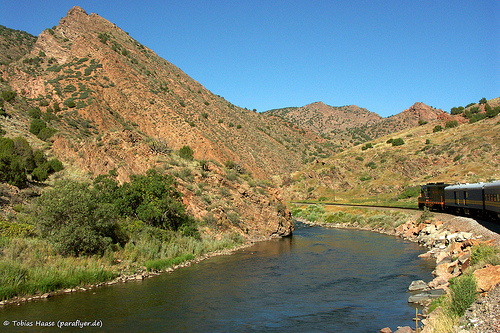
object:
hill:
[16, 2, 280, 200]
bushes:
[447, 109, 460, 115]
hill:
[385, 102, 464, 177]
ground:
[396, 160, 443, 221]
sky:
[4, 2, 496, 122]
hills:
[1, 9, 497, 225]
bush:
[38, 171, 177, 253]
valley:
[175, 59, 486, 237]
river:
[0, 207, 441, 331]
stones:
[474, 264, 500, 294]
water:
[0, 217, 432, 330]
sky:
[2, 0, 498, 98]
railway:
[418, 182, 498, 234]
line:
[293, 200, 419, 210]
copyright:
[0, 315, 107, 331]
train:
[415, 177, 498, 231]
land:
[429, 215, 469, 246]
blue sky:
[228, 29, 330, 89]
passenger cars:
[442, 178, 499, 218]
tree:
[73, 55, 88, 65]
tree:
[63, 82, 78, 94]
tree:
[75, 99, 85, 111]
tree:
[46, 63, 62, 72]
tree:
[37, 125, 54, 141]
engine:
[413, 178, 445, 210]